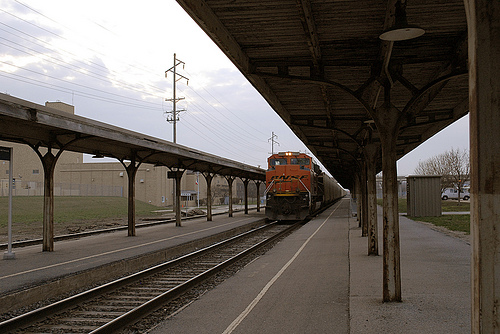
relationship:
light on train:
[282, 139, 302, 159] [242, 138, 327, 237]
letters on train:
[264, 162, 310, 182] [242, 138, 327, 237]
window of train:
[272, 152, 307, 167] [242, 138, 327, 237]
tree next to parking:
[427, 138, 445, 167] [359, 169, 464, 267]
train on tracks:
[242, 138, 327, 237] [12, 204, 288, 334]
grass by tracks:
[97, 189, 112, 210] [12, 204, 288, 334]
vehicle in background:
[447, 176, 472, 197] [412, 153, 457, 234]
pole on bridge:
[0, 149, 15, 257] [253, 6, 463, 189]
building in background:
[90, 169, 173, 202] [412, 153, 457, 234]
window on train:
[272, 152, 307, 167] [242, 138, 327, 237]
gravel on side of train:
[239, 203, 262, 229] [242, 138, 327, 237]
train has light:
[242, 138, 327, 237] [282, 139, 302, 159]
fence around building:
[181, 166, 202, 202] [90, 169, 173, 202]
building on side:
[90, 169, 173, 202] [63, 122, 203, 268]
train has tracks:
[242, 138, 327, 237] [12, 204, 288, 334]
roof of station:
[66, 106, 147, 165] [48, 124, 274, 274]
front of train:
[272, 168, 305, 202] [242, 138, 327, 237]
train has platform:
[242, 138, 327, 237] [102, 195, 225, 312]